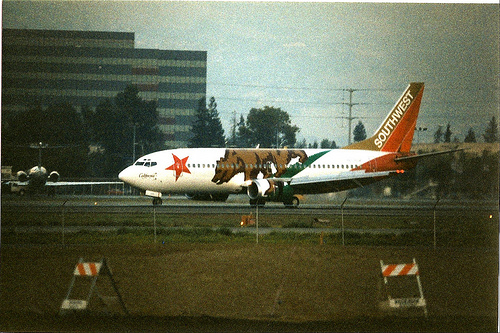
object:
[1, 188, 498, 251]
fence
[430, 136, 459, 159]
ground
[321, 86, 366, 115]
cable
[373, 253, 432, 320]
barrier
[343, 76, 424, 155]
tail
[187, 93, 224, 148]
tree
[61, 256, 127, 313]
post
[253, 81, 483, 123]
three lines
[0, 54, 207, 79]
floor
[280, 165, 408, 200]
add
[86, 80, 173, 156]
trees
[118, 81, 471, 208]
plane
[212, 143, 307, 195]
bear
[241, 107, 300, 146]
tree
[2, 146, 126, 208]
plane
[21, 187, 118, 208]
runway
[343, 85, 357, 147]
power pole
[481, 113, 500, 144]
tree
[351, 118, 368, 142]
tree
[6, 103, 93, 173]
tree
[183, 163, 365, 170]
windows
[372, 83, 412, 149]
letters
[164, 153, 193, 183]
star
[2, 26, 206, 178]
office building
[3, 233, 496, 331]
green grass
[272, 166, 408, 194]
wing